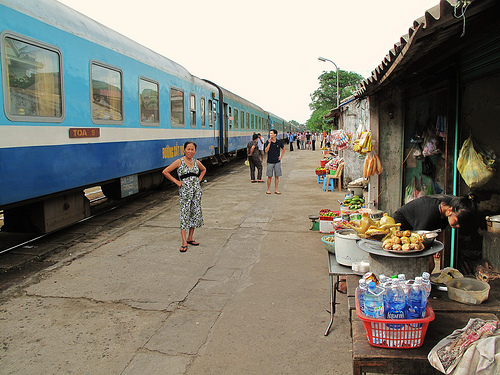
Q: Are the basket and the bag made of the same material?
A: Yes, both the basket and the bag are made of plastic.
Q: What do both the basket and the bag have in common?
A: The material, both the basket and the bag are plastic.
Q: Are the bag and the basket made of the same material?
A: Yes, both the bag and the basket are made of plastic.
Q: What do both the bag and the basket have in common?
A: The material, both the bag and the basket are plastic.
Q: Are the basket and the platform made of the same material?
A: No, the basket is made of plastic and the platform is made of concrete.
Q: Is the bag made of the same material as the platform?
A: No, the bag is made of plastic and the platform is made of cement.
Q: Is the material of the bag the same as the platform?
A: No, the bag is made of plastic and the platform is made of cement.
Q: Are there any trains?
A: Yes, there is a train.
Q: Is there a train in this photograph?
A: Yes, there is a train.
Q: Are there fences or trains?
A: Yes, there is a train.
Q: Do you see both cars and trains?
A: No, there is a train but no cars.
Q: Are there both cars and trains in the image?
A: No, there is a train but no cars.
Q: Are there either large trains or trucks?
A: Yes, there is a large train.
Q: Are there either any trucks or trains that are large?
A: Yes, the train is large.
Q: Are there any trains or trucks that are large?
A: Yes, the train is large.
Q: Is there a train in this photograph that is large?
A: Yes, there is a large train.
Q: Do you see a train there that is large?
A: Yes, there is a train that is large.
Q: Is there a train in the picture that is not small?
A: Yes, there is a large train.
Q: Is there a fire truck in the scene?
A: No, there are no fire trucks.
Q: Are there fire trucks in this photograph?
A: No, there are no fire trucks.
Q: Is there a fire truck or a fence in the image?
A: No, there are no fire trucks or fences.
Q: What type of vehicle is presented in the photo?
A: The vehicle is a train.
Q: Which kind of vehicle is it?
A: The vehicle is a train.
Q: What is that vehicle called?
A: This is a train.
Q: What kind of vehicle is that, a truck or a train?
A: This is a train.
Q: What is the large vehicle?
A: The vehicle is a train.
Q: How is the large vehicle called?
A: The vehicle is a train.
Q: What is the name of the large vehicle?
A: The vehicle is a train.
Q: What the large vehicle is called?
A: The vehicle is a train.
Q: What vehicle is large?
A: The vehicle is a train.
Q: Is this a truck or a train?
A: This is a train.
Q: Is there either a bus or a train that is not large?
A: No, there is a train but it is large.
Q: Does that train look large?
A: Yes, the train is large.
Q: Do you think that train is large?
A: Yes, the train is large.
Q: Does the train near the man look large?
A: Yes, the train is large.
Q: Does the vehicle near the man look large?
A: Yes, the train is large.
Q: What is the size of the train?
A: The train is large.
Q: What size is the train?
A: The train is large.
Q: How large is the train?
A: The train is large.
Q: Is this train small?
A: No, the train is large.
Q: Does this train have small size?
A: No, the train is large.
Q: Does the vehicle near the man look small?
A: No, the train is large.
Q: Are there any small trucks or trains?
A: No, there is a train but it is large.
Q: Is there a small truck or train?
A: No, there is a train but it is large.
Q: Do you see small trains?
A: No, there is a train but it is large.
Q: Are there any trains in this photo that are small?
A: No, there is a train but it is large.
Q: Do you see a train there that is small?
A: No, there is a train but it is large.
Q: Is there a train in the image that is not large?
A: No, there is a train but it is large.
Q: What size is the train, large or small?
A: The train is large.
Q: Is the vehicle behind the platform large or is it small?
A: The train is large.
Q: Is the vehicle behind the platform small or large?
A: The train is large.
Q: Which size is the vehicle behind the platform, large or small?
A: The train is large.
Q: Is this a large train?
A: Yes, this is a large train.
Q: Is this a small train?
A: No, this is a large train.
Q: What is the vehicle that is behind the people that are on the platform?
A: The vehicle is a train.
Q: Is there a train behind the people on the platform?
A: Yes, there is a train behind the people.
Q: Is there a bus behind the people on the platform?
A: No, there is a train behind the people.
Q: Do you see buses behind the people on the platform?
A: No, there is a train behind the people.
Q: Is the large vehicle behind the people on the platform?
A: Yes, the train is behind the people.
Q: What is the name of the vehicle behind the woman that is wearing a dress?
A: The vehicle is a train.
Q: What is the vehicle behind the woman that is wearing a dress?
A: The vehicle is a train.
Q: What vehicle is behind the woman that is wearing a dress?
A: The vehicle is a train.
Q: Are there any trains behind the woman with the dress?
A: Yes, there is a train behind the woman.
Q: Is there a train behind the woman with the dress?
A: Yes, there is a train behind the woman.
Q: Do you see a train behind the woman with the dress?
A: Yes, there is a train behind the woman.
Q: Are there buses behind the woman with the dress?
A: No, there is a train behind the woman.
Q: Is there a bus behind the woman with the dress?
A: No, there is a train behind the woman.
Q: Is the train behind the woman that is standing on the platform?
A: Yes, the train is behind the woman.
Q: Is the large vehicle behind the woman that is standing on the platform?
A: Yes, the train is behind the woman.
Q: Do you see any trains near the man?
A: Yes, there is a train near the man.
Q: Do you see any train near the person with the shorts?
A: Yes, there is a train near the man.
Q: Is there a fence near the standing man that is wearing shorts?
A: No, there is a train near the man.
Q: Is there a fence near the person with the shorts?
A: No, there is a train near the man.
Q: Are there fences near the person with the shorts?
A: No, there is a train near the man.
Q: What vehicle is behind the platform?
A: The vehicle is a train.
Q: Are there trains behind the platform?
A: Yes, there is a train behind the platform.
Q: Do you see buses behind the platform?
A: No, there is a train behind the platform.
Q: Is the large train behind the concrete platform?
A: Yes, the train is behind the platform.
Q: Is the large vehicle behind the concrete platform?
A: Yes, the train is behind the platform.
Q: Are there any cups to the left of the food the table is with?
A: No, there is a train to the left of the food.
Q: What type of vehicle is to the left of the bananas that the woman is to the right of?
A: The vehicle is a train.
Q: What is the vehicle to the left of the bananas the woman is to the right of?
A: The vehicle is a train.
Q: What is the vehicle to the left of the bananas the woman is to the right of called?
A: The vehicle is a train.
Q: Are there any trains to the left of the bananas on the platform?
A: Yes, there is a train to the left of the bananas.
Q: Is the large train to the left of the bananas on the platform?
A: Yes, the train is to the left of the bananas.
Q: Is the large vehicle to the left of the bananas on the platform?
A: Yes, the train is to the left of the bananas.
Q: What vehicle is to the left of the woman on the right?
A: The vehicle is a train.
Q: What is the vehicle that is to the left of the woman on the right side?
A: The vehicle is a train.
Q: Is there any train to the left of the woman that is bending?
A: Yes, there is a train to the left of the woman.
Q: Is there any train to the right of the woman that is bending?
A: No, the train is to the left of the woman.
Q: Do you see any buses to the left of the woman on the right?
A: No, there is a train to the left of the woman.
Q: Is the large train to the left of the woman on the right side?
A: Yes, the train is to the left of the woman.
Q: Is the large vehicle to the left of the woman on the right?
A: Yes, the train is to the left of the woman.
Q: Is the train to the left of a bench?
A: No, the train is to the left of the woman.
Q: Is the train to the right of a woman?
A: No, the train is to the left of a woman.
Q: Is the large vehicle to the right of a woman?
A: No, the train is to the left of a woman.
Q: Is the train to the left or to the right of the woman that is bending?
A: The train is to the left of the woman.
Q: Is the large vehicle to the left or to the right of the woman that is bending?
A: The train is to the left of the woman.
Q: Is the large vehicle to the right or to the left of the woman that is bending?
A: The train is to the left of the woman.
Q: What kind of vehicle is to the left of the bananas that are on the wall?
A: The vehicle is a train.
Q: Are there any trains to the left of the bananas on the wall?
A: Yes, there is a train to the left of the bananas.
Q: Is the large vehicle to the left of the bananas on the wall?
A: Yes, the train is to the left of the bananas.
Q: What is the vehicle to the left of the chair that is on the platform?
A: The vehicle is a train.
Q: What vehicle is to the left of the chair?
A: The vehicle is a train.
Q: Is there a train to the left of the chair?
A: Yes, there is a train to the left of the chair.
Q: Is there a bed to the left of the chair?
A: No, there is a train to the left of the chair.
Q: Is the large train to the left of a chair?
A: Yes, the train is to the left of a chair.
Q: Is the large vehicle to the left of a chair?
A: Yes, the train is to the left of a chair.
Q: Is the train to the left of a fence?
A: No, the train is to the left of a chair.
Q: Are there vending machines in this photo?
A: No, there are no vending machines.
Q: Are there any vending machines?
A: No, there are no vending machines.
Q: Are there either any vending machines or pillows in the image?
A: No, there are no vending machines or pillows.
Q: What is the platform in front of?
A: The platform is in front of the train.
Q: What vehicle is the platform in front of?
A: The platform is in front of the train.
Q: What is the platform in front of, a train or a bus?
A: The platform is in front of a train.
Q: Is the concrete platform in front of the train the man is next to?
A: Yes, the platform is in front of the train.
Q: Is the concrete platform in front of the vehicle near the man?
A: Yes, the platform is in front of the train.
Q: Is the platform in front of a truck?
A: No, the platform is in front of the train.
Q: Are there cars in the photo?
A: No, there are no cars.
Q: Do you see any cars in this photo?
A: No, there are no cars.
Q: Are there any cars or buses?
A: No, there are no cars or buses.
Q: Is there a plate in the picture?
A: Yes, there is a plate.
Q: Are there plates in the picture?
A: Yes, there is a plate.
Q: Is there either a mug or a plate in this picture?
A: Yes, there is a plate.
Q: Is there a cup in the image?
A: No, there are no cups.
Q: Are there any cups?
A: No, there are no cups.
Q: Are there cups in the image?
A: No, there are no cups.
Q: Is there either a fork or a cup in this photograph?
A: No, there are no cups or forks.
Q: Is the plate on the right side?
A: Yes, the plate is on the right of the image.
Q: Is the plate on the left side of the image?
A: No, the plate is on the right of the image.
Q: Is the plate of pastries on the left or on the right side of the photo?
A: The plate is on the right of the image.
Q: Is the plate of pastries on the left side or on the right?
A: The plate is on the right of the image.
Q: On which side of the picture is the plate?
A: The plate is on the right of the image.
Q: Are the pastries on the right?
A: Yes, the pastries are on the right of the image.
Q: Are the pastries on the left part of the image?
A: No, the pastries are on the right of the image.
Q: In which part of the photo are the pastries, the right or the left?
A: The pastries are on the right of the image.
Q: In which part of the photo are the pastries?
A: The pastries are on the right of the image.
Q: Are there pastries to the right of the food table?
A: Yes, there are pastries to the right of the table.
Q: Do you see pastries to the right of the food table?
A: Yes, there are pastries to the right of the table.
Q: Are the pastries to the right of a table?
A: Yes, the pastries are to the right of a table.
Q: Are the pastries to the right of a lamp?
A: No, the pastries are to the right of a table.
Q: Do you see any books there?
A: No, there are no books.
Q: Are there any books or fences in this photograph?
A: No, there are no books or fences.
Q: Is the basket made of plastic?
A: Yes, the basket is made of plastic.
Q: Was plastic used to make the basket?
A: Yes, the basket is made of plastic.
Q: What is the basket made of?
A: The basket is made of plastic.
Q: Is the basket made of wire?
A: No, the basket is made of plastic.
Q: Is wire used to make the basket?
A: No, the basket is made of plastic.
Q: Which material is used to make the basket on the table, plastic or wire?
A: The basket is made of plastic.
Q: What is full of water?
A: The basket is full of water.